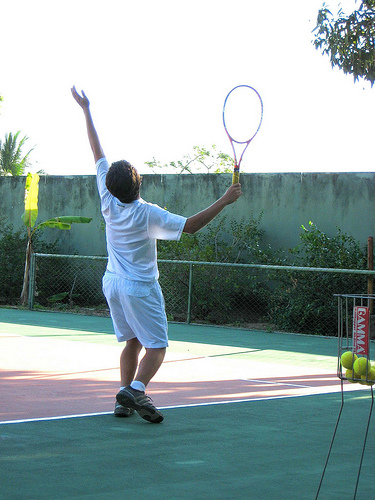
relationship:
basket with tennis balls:
[315, 293, 372, 498] [340, 351, 373, 383]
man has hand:
[49, 66, 275, 426] [65, 84, 91, 108]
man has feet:
[49, 66, 275, 426] [115, 385, 175, 423]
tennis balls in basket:
[340, 351, 363, 385] [315, 291, 363, 498]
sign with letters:
[350, 305, 362, 357] [355, 309, 363, 351]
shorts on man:
[101, 267, 170, 349] [49, 66, 275, 426]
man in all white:
[49, 66, 275, 426] [338, 342, 370, 401]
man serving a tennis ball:
[49, 66, 275, 426] [76, 194, 213, 363]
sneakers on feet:
[105, 389, 182, 418] [105, 389, 175, 423]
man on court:
[49, 66, 275, 426] [2, 306, 363, 494]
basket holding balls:
[315, 293, 372, 498] [332, 347, 363, 382]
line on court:
[3, 372, 336, 427] [2, 306, 363, 494]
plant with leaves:
[18, 170, 92, 304] [22, 171, 90, 233]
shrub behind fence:
[255, 219, 362, 334] [26, 251, 362, 336]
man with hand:
[49, 66, 275, 426] [68, 85, 89, 108]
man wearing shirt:
[49, 66, 275, 426] [95, 156, 184, 282]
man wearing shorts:
[49, 66, 275, 426] [101, 267, 170, 349]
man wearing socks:
[49, 66, 275, 426] [114, 378, 150, 392]